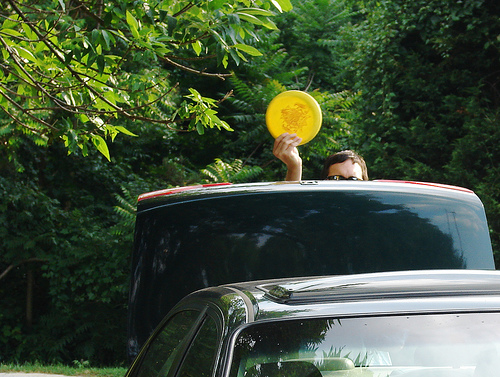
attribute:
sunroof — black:
[261, 264, 498, 304]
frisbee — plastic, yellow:
[256, 75, 331, 147]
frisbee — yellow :
[266, 87, 323, 148]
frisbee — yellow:
[264, 88, 322, 143]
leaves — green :
[23, 46, 125, 228]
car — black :
[126, 179, 493, 375]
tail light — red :
[132, 176, 235, 203]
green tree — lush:
[0, 3, 292, 180]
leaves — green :
[0, 2, 295, 149]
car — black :
[95, 154, 493, 374]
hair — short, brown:
[326, 149, 366, 179]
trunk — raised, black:
[132, 180, 499, 359]